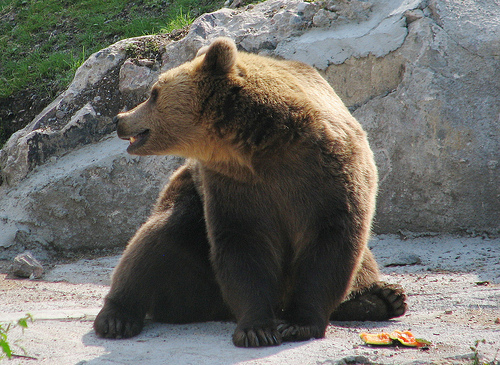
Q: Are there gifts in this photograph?
A: No, there are no gifts.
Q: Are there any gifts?
A: No, there are no gifts.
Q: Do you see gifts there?
A: No, there are no gifts.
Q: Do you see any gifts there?
A: No, there are no gifts.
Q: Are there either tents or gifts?
A: No, there are no gifts or tents.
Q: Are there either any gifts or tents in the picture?
A: No, there are no gifts or tents.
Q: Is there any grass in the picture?
A: Yes, there is grass.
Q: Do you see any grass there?
A: Yes, there is grass.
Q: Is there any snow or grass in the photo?
A: Yes, there is grass.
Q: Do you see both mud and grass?
A: No, there is grass but no mud.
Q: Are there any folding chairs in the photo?
A: No, there are no folding chairs.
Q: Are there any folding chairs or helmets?
A: No, there are no folding chairs or helmets.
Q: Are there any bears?
A: Yes, there is a bear.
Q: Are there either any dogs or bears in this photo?
A: Yes, there is a bear.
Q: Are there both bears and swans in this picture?
A: No, there is a bear but no swans.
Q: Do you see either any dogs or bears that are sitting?
A: Yes, the bear is sitting.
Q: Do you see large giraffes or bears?
A: Yes, there is a large bear.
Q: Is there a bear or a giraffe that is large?
A: Yes, the bear is large.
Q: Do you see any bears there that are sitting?
A: Yes, there is a bear that is sitting.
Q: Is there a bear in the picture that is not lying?
A: Yes, there is a bear that is sitting.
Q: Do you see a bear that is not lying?
A: Yes, there is a bear that is sitting .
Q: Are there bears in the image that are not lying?
A: Yes, there is a bear that is sitting.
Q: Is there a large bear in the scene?
A: Yes, there is a large bear.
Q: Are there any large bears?
A: Yes, there is a large bear.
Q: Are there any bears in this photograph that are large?
A: Yes, there is a bear that is large.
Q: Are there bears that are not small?
A: Yes, there is a large bear.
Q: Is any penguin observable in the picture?
A: No, there are no penguins.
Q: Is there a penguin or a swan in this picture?
A: No, there are no penguins or swans.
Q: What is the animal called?
A: The animal is a bear.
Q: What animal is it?
A: The animal is a bear.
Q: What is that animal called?
A: That is a bear.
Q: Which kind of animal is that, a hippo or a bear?
A: That is a bear.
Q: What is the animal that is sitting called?
A: The animal is a bear.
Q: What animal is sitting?
A: The animal is a bear.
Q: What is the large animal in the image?
A: The animal is a bear.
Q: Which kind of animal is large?
A: The animal is a bear.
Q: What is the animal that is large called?
A: The animal is a bear.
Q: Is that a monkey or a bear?
A: That is a bear.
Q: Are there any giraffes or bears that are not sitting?
A: No, there is a bear but it is sitting.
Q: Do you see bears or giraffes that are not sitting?
A: No, there is a bear but it is sitting.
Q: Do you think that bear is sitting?
A: Yes, the bear is sitting.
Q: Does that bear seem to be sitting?
A: Yes, the bear is sitting.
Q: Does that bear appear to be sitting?
A: Yes, the bear is sitting.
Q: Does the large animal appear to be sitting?
A: Yes, the bear is sitting.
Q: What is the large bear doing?
A: The bear is sitting.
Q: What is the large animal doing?
A: The bear is sitting.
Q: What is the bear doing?
A: The bear is sitting.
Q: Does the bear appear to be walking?
A: No, the bear is sitting.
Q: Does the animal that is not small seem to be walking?
A: No, the bear is sitting.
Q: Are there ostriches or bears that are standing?
A: No, there is a bear but it is sitting.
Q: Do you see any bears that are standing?
A: No, there is a bear but it is sitting.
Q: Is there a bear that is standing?
A: No, there is a bear but it is sitting.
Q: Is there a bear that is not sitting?
A: No, there is a bear but it is sitting.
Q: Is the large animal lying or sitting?
A: The bear is sitting.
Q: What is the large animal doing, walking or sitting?
A: The bear is sitting.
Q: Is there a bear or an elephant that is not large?
A: No, there is a bear but it is large.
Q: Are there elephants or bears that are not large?
A: No, there is a bear but it is large.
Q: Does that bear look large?
A: Yes, the bear is large.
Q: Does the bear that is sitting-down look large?
A: Yes, the bear is large.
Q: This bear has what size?
A: The bear is large.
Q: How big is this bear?
A: The bear is large.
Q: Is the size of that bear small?
A: No, the bear is large.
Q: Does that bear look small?
A: No, the bear is large.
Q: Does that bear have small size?
A: No, the bear is large.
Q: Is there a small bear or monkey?
A: No, there is a bear but it is large.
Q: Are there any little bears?
A: No, there is a bear but it is large.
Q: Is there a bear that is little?
A: No, there is a bear but it is large.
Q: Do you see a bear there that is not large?
A: No, there is a bear but it is large.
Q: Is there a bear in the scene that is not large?
A: No, there is a bear but it is large.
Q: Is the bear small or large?
A: The bear is large.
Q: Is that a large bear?
A: Yes, that is a large bear.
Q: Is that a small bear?
A: No, that is a large bear.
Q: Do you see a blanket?
A: No, there are no blankets.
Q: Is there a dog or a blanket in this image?
A: No, there are no blankets or dogs.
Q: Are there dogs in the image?
A: No, there are no dogs.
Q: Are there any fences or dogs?
A: No, there are no dogs or fences.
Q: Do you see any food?
A: Yes, there is food.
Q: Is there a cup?
A: No, there are no cups.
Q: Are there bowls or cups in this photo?
A: No, there are no cups or bowls.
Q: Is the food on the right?
A: Yes, the food is on the right of the image.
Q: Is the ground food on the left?
A: No, the food is on the right of the image.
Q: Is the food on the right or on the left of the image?
A: The food is on the right of the image.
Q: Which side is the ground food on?
A: The food is on the right of the image.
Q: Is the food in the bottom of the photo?
A: Yes, the food is in the bottom of the image.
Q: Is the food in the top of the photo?
A: No, the food is in the bottom of the image.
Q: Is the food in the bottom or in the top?
A: The food is in the bottom of the image.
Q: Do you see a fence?
A: No, there are no fences.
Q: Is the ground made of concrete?
A: Yes, the ground is made of concrete.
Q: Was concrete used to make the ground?
A: Yes, the ground is made of concrete.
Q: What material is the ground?
A: The ground is made of concrete.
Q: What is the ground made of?
A: The ground is made of concrete.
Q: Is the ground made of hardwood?
A: No, the ground is made of cement.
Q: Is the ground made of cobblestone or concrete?
A: The ground is made of concrete.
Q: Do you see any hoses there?
A: No, there are no hoses.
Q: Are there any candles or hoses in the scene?
A: No, there are no hoses or candles.